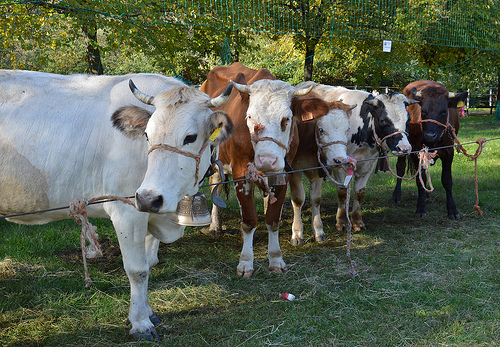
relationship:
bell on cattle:
[174, 195, 213, 227] [0, 69, 233, 342]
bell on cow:
[268, 172, 288, 185] [201, 62, 320, 278]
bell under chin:
[174, 195, 213, 227] [135, 184, 213, 214]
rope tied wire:
[71, 195, 135, 288] [0, 130, 499, 231]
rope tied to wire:
[248, 164, 277, 206] [0, 130, 499, 231]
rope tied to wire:
[332, 155, 357, 186] [0, 130, 499, 231]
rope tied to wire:
[380, 146, 435, 192] [0, 130, 499, 231]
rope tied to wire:
[463, 138, 483, 218] [0, 130, 499, 231]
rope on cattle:
[71, 138, 483, 215] [2, 60, 468, 328]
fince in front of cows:
[2, 1, 497, 53] [2, 60, 468, 328]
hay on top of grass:
[381, 235, 472, 299] [8, 226, 492, 342]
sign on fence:
[382, 38, 392, 53] [2, 1, 497, 53]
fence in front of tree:
[2, 1, 497, 53] [287, 2, 330, 81]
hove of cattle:
[128, 310, 163, 342] [2, 60, 468, 328]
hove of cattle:
[236, 262, 290, 279] [2, 60, 468, 328]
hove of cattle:
[291, 230, 328, 247] [2, 60, 468, 328]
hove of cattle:
[336, 216, 366, 234] [2, 60, 468, 328]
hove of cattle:
[414, 206, 462, 219] [2, 60, 468, 328]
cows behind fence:
[2, 60, 468, 328] [2, 1, 497, 53]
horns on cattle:
[127, 80, 236, 106] [0, 69, 233, 342]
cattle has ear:
[0, 69, 233, 342] [112, 104, 154, 138]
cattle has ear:
[0, 69, 233, 342] [209, 110, 233, 144]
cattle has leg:
[0, 69, 233, 342] [99, 184, 162, 335]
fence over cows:
[2, 1, 497, 53] [2, 60, 468, 328]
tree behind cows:
[287, 2, 330, 81] [2, 60, 468, 328]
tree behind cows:
[46, 1, 111, 74] [2, 60, 468, 328]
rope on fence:
[463, 138, 483, 218] [0, 130, 499, 231]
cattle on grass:
[0, 69, 233, 342] [8, 226, 492, 342]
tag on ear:
[211, 122, 224, 142] [209, 110, 233, 144]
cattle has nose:
[0, 69, 233, 342] [135, 184, 180, 217]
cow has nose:
[201, 62, 320, 278] [253, 152, 285, 172]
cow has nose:
[292, 104, 355, 245] [324, 155, 350, 169]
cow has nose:
[336, 95, 409, 231] [388, 140, 411, 155]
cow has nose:
[397, 79, 462, 219] [422, 127, 441, 143]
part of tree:
[294, 5, 320, 79] [287, 2, 330, 81]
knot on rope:
[66, 199, 87, 223] [71, 195, 135, 288]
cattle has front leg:
[0, 69, 233, 342] [99, 184, 162, 335]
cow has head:
[336, 95, 409, 231] [374, 96, 412, 158]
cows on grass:
[2, 60, 468, 328] [8, 226, 492, 342]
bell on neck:
[174, 195, 213, 227] [140, 173, 219, 205]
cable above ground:
[0, 130, 499, 231] [8, 226, 492, 342]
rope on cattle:
[71, 195, 135, 288] [0, 69, 233, 342]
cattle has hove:
[0, 69, 233, 342] [128, 310, 163, 342]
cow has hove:
[201, 62, 320, 278] [236, 262, 290, 279]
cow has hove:
[292, 104, 355, 245] [291, 230, 328, 247]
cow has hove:
[336, 95, 409, 231] [336, 216, 366, 234]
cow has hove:
[397, 79, 462, 219] [414, 206, 462, 219]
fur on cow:
[202, 64, 233, 100] [397, 79, 462, 219]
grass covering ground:
[8, 226, 492, 342] [0, 108, 498, 343]